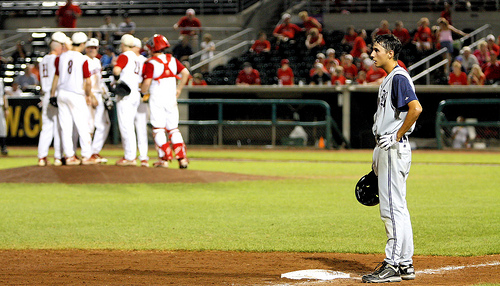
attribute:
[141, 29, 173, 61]
helmet — red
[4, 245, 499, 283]
clay — red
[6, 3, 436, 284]
baseball game — night time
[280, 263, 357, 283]
plate — white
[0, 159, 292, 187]
mound — brown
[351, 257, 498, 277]
lines — white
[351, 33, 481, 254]
baseball player — standing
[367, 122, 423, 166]
ground — green, grass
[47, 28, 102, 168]
baseball player — standing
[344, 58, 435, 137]
shirts — red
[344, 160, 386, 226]
helmet — held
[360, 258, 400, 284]
shoes — black